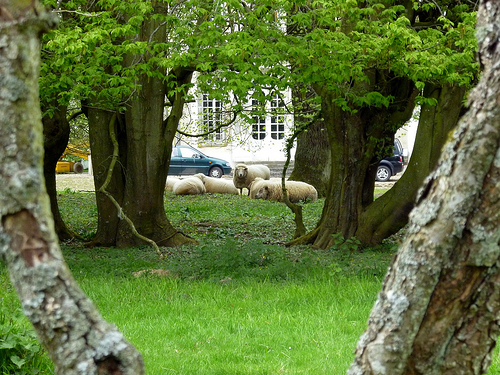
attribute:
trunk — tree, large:
[103, 121, 160, 249]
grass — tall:
[108, 257, 365, 327]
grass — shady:
[156, 216, 312, 298]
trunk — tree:
[114, 103, 202, 203]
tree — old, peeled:
[382, 32, 497, 353]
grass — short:
[2, 187, 499, 372]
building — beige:
[165, 5, 297, 157]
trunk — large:
[86, 61, 183, 264]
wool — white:
[289, 180, 309, 197]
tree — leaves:
[281, 0, 466, 248]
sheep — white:
[172, 175, 206, 196]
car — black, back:
[360, 129, 405, 187]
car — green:
[168, 143, 232, 181]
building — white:
[164, 5, 424, 165]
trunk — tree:
[385, 254, 495, 357]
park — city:
[1, 2, 497, 371]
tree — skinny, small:
[5, 196, 106, 373]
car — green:
[174, 134, 224, 182]